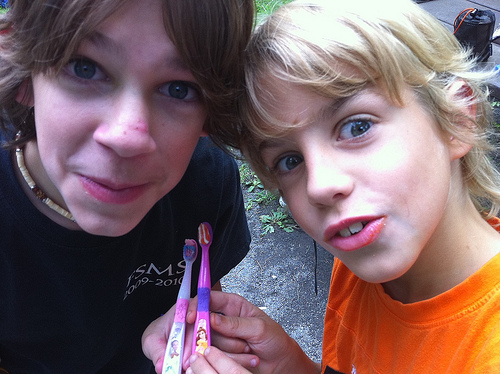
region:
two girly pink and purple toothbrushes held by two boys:
[152, 211, 252, 372]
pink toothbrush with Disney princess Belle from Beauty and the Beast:
[195, 220, 215, 361]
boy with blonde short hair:
[240, 3, 499, 300]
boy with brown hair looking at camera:
[2, 0, 257, 255]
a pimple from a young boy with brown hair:
[126, 100, 151, 140]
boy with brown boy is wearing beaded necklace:
[7, 118, 77, 236]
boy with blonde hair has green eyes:
[265, 112, 388, 184]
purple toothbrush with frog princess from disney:
[152, 235, 201, 372]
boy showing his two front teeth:
[314, 204, 418, 257]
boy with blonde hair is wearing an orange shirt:
[235, 2, 498, 372]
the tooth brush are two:
[150, 230, 234, 372]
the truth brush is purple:
[190, 222, 247, 366]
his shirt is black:
[42, 261, 137, 358]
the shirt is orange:
[329, 295, 466, 356]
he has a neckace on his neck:
[17, 164, 87, 225]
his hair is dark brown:
[172, 20, 247, 107]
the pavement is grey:
[263, 258, 332, 313]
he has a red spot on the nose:
[123, 113, 158, 144]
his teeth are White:
[346, 220, 409, 270]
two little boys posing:
[10, 1, 495, 301]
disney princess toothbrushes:
[169, 221, 217, 372]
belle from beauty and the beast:
[195, 215, 216, 372]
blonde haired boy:
[258, 4, 498, 283]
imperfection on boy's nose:
[98, 101, 153, 169]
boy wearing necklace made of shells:
[0, 144, 84, 249]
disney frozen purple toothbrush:
[172, 233, 189, 373]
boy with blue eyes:
[250, 104, 387, 181]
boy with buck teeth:
[312, 206, 389, 254]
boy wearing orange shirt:
[273, 247, 498, 372]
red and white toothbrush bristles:
[196, 218, 212, 246]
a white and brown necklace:
[9, 121, 88, 225]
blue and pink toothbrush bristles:
[181, 235, 198, 265]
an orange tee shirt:
[318, 207, 498, 372]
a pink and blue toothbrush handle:
[191, 237, 215, 359]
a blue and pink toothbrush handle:
[156, 259, 194, 372]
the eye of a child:
[331, 110, 382, 147]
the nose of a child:
[91, 82, 159, 159]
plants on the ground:
[255, 202, 298, 237]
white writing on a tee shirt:
[117, 257, 194, 299]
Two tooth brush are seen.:
[146, 228, 221, 358]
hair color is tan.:
[289, 5, 414, 70]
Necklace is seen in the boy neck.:
[3, 146, 74, 238]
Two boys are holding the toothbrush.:
[18, 70, 381, 372]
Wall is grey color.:
[263, 255, 318, 301]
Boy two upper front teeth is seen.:
[316, 213, 393, 267]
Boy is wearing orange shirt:
[316, 277, 491, 368]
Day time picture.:
[19, 76, 448, 303]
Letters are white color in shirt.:
[116, 251, 195, 305]